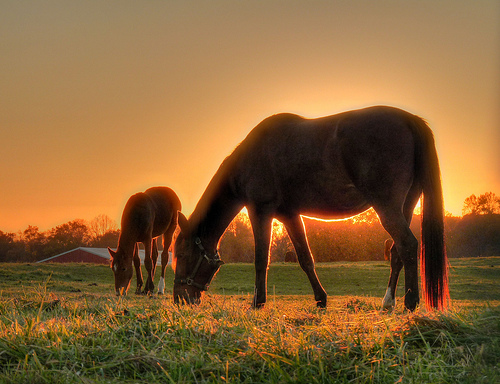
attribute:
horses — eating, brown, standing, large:
[101, 100, 453, 306]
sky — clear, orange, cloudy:
[6, 3, 494, 230]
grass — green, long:
[1, 274, 494, 377]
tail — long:
[410, 124, 448, 312]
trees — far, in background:
[2, 222, 490, 252]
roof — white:
[39, 251, 175, 262]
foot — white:
[382, 290, 395, 316]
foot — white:
[157, 279, 167, 294]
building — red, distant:
[41, 250, 116, 260]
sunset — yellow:
[418, 89, 496, 208]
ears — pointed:
[177, 211, 193, 240]